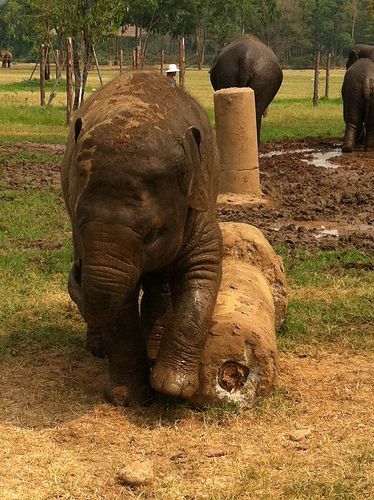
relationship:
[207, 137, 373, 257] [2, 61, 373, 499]
mud on ground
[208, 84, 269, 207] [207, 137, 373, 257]
pillar in mud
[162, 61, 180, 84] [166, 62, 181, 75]
man wearing a hat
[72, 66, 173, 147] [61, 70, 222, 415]
mud on elephant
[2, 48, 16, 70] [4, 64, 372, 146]
elephant standing in grass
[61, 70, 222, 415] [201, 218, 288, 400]
elephant standing near pillar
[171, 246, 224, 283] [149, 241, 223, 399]
wrinkles on leg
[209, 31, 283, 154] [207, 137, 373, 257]
elephant standing in mud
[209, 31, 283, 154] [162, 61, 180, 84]
elephant stands near man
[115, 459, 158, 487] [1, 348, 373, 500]
rock in grass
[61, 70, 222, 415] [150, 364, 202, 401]
elephant has a foot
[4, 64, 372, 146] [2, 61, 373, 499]
grass on ground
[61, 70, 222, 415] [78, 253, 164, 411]
elephant has a trunk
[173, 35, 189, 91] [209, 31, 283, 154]
tree trunk next to elephant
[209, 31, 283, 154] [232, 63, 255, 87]
elephant has a tail